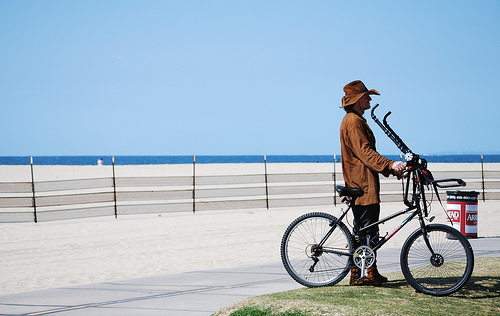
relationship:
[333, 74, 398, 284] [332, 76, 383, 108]
man wearing hat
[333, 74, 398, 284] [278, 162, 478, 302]
man holds bike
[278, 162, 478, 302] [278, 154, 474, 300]
bike held up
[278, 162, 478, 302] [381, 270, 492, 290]
bike casts shadow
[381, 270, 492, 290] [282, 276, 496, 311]
shadow on grass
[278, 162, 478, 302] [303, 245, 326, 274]
bike has pedal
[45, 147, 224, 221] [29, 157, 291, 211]
beach has fence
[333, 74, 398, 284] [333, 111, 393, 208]
man wears jacket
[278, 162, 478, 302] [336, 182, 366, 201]
bike has seat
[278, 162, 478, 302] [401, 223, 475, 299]
bike has tire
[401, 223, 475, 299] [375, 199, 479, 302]
tire in front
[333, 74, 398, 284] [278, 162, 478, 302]
man has bicycle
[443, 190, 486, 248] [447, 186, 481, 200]
trash can holds trash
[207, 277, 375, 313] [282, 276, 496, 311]
patches of grass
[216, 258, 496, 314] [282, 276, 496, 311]
areas of grass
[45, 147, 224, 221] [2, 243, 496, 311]
beach has trail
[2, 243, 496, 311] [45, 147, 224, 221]
trail near beach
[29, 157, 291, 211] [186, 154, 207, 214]
fence has pole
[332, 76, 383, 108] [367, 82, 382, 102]
hat has brim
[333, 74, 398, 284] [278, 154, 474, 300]
man stands up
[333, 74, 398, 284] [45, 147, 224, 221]
man near beach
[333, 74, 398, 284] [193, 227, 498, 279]
man near path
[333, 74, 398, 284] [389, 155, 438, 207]
man holds handlebars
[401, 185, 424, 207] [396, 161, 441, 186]
bar has handles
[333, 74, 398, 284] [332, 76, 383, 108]
man wears hat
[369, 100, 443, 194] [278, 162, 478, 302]
objects on bicycle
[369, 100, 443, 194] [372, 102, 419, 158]
objects resemble clarients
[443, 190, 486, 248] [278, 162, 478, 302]
garbage can behind bicycle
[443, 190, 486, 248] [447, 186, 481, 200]
garbage can holds garbage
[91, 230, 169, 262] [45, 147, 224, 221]
sand at beach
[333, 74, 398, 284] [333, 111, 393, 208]
man wears coat